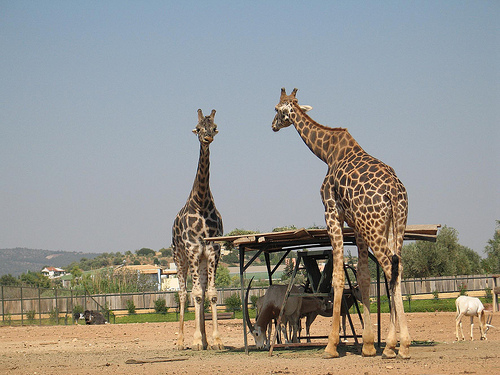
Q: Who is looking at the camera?
A: Giraffe.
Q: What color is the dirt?
A: Brown.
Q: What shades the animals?
A: A structure.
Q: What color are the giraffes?
A: Brown and white.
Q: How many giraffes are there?
A: Two.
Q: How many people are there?
A: None.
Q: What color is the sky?
A: Blue.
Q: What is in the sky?
A: Nothing.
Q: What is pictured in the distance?
A: Green trees.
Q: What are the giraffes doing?
A: Facing each other.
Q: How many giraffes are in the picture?
A: Two.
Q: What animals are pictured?
A: Giraffes.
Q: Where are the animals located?
A: Outside in the habitat.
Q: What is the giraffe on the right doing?
A: Looking at the other giraffe.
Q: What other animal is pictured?
A: Antelope.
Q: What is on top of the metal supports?
A: Brown boards.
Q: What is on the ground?
A: Pebbles.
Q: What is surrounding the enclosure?
A: Wood fence.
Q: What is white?
A: Animal to the right.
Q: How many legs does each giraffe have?
A: Four.